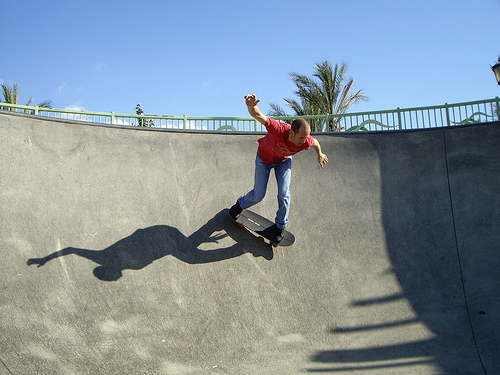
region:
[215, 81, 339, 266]
Skater in a skate trail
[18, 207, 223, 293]
Shadow of skater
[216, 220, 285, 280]
Shadow of skateboard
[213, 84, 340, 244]
Person wears a red t-shirt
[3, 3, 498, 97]
Sky is blue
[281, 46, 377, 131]
Plant in a park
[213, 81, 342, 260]
Skater has extended arms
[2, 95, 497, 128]
Fence around skate trail is metal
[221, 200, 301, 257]
Skateboard is black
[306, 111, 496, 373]
Shadow cast on skate trail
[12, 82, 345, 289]
Skater is casting a shadow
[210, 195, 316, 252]
Top of the Skateboard is black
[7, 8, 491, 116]
The sky is clear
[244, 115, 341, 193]
Skater is wearing a red shirt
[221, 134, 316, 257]
Skater is wearing blue jeans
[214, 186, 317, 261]
Skater is wearing black shoes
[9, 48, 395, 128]
Trees are in the background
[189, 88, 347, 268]
Skater is riding down a ram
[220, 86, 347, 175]
Skater has his hand in the air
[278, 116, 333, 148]
Skater's hair is short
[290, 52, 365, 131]
fronds of a palm tree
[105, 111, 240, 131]
green metal fencing rails and posts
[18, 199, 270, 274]
a shadow on concrete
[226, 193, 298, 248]
a black skateboard being used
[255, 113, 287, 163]
a red short-sleeved shirt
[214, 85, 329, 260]
a man on a skateboard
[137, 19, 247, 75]
a patch of pure blue afternoon sky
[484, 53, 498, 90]
the edge of an unlit street lamp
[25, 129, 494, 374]
a concrete skateboard park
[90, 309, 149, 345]
an off-white patch of concrete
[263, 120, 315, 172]
The skateboarder's red t-shirt.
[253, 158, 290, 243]
The skateboarder's blue jeans.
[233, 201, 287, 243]
The skateboarder's black shoes.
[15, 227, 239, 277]
The shadow of the skateboarder.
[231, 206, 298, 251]
The black skateboard the skater is riding on.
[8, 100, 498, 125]
The green bar fence around the ramp.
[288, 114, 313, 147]
The bald head of the skateboarder.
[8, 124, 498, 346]
The ramp the skateboarder is riding on.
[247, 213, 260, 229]
The white lettering on the skateboard.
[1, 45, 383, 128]
The palm trees behind the ramp.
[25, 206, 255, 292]
a shadow cast on the ground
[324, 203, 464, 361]
a large cement skate pit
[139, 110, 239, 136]
a green railing enclosing the pit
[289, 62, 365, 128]
a palm tree growing nearby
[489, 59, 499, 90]
a street light near the fence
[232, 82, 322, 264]
a man wearing a red shirt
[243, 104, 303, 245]
a man wearing blue jeans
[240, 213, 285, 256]
a black skateboard supporting a man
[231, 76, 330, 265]
a man preparing to do a stunt